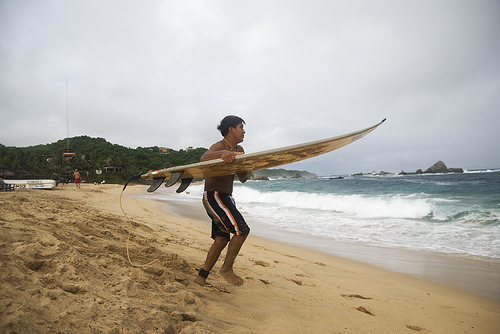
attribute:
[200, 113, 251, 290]
man — young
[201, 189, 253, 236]
shorts — black, dirty, red, striped, white, orange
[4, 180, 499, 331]
sand — brown, wet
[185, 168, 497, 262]
water — blue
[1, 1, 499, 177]
sky — gray, cloudy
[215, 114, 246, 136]
hair — dark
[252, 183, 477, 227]
waves — crushing, white, breaking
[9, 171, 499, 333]
beach — sandy, clean, disturbed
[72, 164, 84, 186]
person — walking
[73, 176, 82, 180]
pants — red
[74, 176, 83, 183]
shorts — red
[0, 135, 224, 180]
trees — green